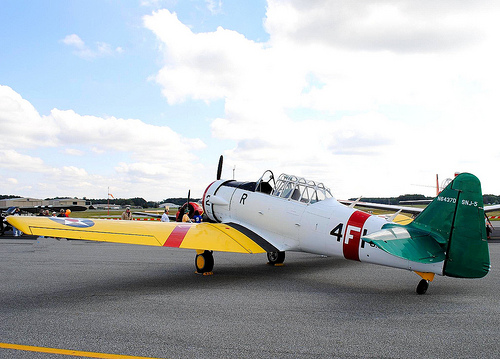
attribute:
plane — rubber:
[3, 159, 489, 296]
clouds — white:
[2, 0, 499, 181]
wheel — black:
[193, 246, 213, 281]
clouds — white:
[337, 15, 417, 127]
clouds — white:
[144, 12, 268, 123]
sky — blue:
[7, 10, 161, 117]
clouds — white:
[348, 54, 430, 99]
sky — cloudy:
[1, 0, 446, 158]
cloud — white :
[3, 88, 189, 160]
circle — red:
[50, 215, 98, 229]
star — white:
[53, 216, 90, 227]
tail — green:
[359, 170, 494, 287]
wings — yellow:
[31, 190, 279, 311]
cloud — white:
[151, 0, 497, 112]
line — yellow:
[0, 342, 154, 357]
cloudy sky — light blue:
[154, 36, 484, 135]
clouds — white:
[127, 3, 280, 130]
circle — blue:
[48, 215, 95, 227]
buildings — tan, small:
[3, 195, 95, 212]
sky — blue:
[2, 2, 481, 173]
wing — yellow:
[4, 214, 275, 256]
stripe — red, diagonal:
[160, 217, 199, 247]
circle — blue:
[49, 209, 95, 227]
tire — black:
[196, 242, 217, 277]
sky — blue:
[0, 0, 499, 207]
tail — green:
[372, 172, 493, 282]